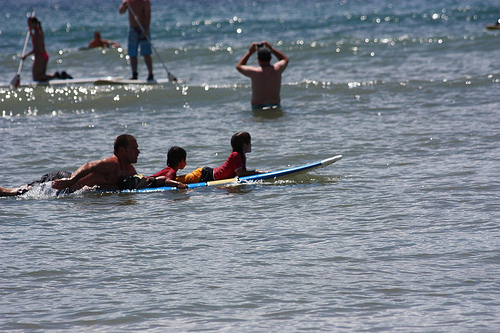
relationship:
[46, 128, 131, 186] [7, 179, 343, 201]
man on surfboard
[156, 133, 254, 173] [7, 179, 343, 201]
children on surfboard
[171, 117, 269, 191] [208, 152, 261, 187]
child has shirt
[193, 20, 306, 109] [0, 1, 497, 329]
man standing on water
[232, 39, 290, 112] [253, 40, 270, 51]
man holds camera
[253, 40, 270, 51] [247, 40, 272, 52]
camera on hands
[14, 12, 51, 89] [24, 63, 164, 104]
woman on paddle board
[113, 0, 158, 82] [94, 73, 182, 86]
man on board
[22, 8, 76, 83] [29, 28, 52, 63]
woman dress bikini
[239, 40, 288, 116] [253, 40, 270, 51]
man has camera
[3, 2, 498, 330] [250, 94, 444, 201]
open day in sea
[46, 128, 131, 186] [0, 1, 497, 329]
man in water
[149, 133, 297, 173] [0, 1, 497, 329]
children in water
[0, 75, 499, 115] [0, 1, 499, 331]
wave in ocean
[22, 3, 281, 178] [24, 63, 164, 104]
people on paddle board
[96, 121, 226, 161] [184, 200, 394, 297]
people swimming in water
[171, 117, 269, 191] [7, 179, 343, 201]
child on surfboard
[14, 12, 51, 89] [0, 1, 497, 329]
woman paddling water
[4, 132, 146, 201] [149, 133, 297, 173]
man pushing children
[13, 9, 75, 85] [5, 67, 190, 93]
person kneeling on paddleboard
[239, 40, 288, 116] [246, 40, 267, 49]
man with camera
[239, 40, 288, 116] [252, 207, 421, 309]
man in water